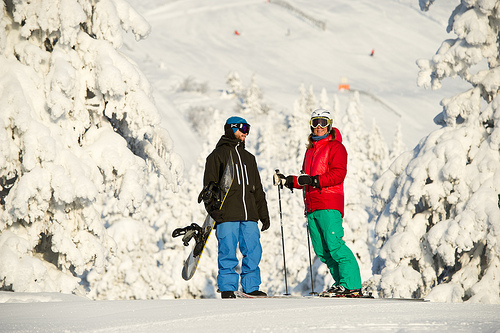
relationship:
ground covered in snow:
[1, 296, 495, 331] [100, 316, 399, 328]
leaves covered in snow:
[415, 36, 496, 91] [16, 104, 66, 177]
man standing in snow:
[272, 108, 363, 294] [78, 299, 205, 332]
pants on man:
[298, 195, 367, 294] [272, 109, 364, 297]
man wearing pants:
[272, 109, 364, 297] [290, 203, 380, 302]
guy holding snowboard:
[197, 116, 270, 299] [146, 214, 245, 285]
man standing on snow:
[272, 109, 364, 297] [148, 292, 362, 329]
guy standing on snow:
[197, 116, 270, 299] [148, 292, 362, 329]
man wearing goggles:
[272, 109, 364, 297] [232, 122, 257, 142]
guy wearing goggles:
[197, 116, 270, 299] [298, 111, 332, 131]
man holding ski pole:
[272, 109, 364, 297] [271, 168, 291, 295]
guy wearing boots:
[197, 116, 270, 299] [218, 289, 269, 302]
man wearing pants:
[272, 109, 364, 297] [302, 207, 362, 287]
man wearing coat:
[272, 109, 364, 297] [291, 136, 348, 215]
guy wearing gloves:
[197, 116, 270, 299] [259, 210, 270, 237]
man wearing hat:
[272, 109, 364, 297] [309, 111, 333, 122]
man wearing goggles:
[272, 109, 364, 297] [309, 118, 334, 128]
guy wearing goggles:
[197, 116, 270, 299] [235, 122, 249, 135]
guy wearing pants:
[197, 116, 270, 299] [214, 220, 264, 295]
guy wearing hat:
[193, 114, 292, 292] [226, 118, 247, 135]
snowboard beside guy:
[175, 161, 237, 281] [197, 116, 270, 299]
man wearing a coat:
[272, 109, 364, 297] [286, 128, 349, 216]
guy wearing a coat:
[197, 116, 270, 299] [195, 125, 272, 228]